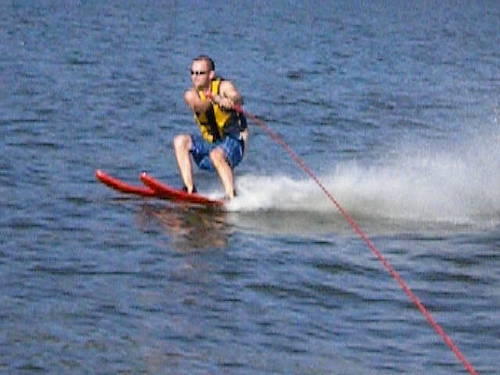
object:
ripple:
[317, 258, 380, 279]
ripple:
[349, 343, 381, 356]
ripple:
[301, 97, 332, 109]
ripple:
[216, 265, 258, 277]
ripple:
[28, 259, 81, 276]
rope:
[205, 91, 478, 375]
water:
[0, 0, 500, 375]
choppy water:
[192, 115, 500, 238]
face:
[191, 60, 208, 87]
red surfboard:
[95, 168, 223, 205]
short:
[186, 135, 244, 172]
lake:
[0, 0, 500, 375]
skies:
[0, 0, 500, 38]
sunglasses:
[191, 69, 210, 74]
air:
[0, 0, 500, 375]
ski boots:
[221, 197, 239, 204]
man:
[173, 55, 248, 201]